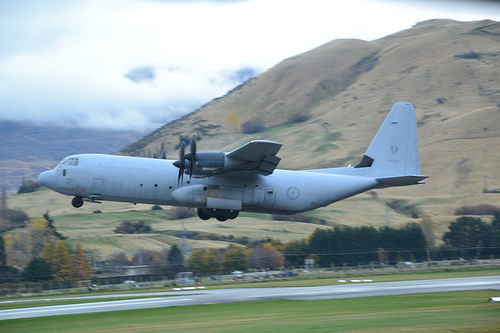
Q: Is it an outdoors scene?
A: Yes, it is outdoors.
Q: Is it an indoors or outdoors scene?
A: It is outdoors.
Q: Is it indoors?
A: No, it is outdoors.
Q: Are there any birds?
A: No, there are no birds.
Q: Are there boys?
A: No, there are no boys.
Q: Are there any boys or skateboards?
A: No, there are no boys or skateboards.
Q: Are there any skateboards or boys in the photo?
A: No, there are no boys or skateboards.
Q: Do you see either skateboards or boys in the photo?
A: No, there are no boys or skateboards.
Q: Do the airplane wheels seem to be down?
A: Yes, the wheels are down.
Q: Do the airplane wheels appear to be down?
A: Yes, the wheels are down.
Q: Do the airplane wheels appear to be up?
A: No, the wheels are down.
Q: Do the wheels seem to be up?
A: No, the wheels are down.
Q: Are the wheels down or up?
A: The wheels are down.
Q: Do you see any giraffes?
A: No, there are no giraffes.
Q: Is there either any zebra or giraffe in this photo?
A: No, there are no giraffes or zebras.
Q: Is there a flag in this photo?
A: No, there are no flags.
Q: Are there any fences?
A: Yes, there is a fence.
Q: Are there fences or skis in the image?
A: Yes, there is a fence.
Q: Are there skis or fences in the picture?
A: Yes, there is a fence.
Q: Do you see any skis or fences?
A: Yes, there is a fence.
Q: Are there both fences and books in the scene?
A: No, there is a fence but no books.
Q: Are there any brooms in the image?
A: No, there are no brooms.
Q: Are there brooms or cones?
A: No, there are no brooms or cones.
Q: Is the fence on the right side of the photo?
A: Yes, the fence is on the right of the image.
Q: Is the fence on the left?
A: No, the fence is on the right of the image.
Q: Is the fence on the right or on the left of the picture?
A: The fence is on the right of the image.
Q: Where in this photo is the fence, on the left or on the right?
A: The fence is on the right of the image.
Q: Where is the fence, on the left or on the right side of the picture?
A: The fence is on the right of the image.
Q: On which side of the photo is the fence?
A: The fence is on the right of the image.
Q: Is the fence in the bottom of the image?
A: Yes, the fence is in the bottom of the image.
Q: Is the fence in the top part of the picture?
A: No, the fence is in the bottom of the image.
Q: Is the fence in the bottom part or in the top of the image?
A: The fence is in the bottom of the image.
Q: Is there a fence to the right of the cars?
A: Yes, there is a fence to the right of the cars.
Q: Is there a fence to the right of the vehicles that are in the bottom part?
A: Yes, there is a fence to the right of the cars.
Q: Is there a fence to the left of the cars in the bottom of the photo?
A: No, the fence is to the right of the cars.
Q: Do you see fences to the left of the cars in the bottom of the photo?
A: No, the fence is to the right of the cars.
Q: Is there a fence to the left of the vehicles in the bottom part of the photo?
A: No, the fence is to the right of the cars.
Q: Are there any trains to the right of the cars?
A: No, there is a fence to the right of the cars.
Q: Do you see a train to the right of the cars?
A: No, there is a fence to the right of the cars.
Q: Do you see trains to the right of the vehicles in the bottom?
A: No, there is a fence to the right of the cars.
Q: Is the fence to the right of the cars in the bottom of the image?
A: Yes, the fence is to the right of the cars.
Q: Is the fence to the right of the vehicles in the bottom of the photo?
A: Yes, the fence is to the right of the cars.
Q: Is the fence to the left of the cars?
A: No, the fence is to the right of the cars.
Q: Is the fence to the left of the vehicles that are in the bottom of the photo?
A: No, the fence is to the right of the cars.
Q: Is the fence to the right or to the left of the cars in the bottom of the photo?
A: The fence is to the right of the cars.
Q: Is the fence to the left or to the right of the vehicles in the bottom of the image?
A: The fence is to the right of the cars.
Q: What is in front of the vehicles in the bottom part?
A: The fence is in front of the cars.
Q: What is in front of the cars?
A: The fence is in front of the cars.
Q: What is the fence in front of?
A: The fence is in front of the cars.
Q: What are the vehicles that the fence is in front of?
A: The vehicles are cars.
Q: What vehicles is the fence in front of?
A: The fence is in front of the cars.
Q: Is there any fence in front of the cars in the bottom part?
A: Yes, there is a fence in front of the cars.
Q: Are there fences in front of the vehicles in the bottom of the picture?
A: Yes, there is a fence in front of the cars.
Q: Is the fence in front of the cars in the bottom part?
A: Yes, the fence is in front of the cars.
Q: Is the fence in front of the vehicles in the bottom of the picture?
A: Yes, the fence is in front of the cars.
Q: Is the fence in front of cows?
A: No, the fence is in front of the cars.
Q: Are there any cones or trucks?
A: No, there are no trucks or cones.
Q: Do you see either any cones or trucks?
A: No, there are no trucks or cones.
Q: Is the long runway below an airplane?
A: Yes, the runway is below an airplane.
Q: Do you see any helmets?
A: No, there are no helmets.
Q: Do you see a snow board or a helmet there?
A: No, there are no helmets or snowboards.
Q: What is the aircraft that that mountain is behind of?
A: The aircraft is an airplane.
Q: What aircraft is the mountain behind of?
A: The mountain is behind the plane.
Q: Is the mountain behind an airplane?
A: Yes, the mountain is behind an airplane.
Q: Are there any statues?
A: No, there are no statues.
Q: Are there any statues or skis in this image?
A: No, there are no statues or skis.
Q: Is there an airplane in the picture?
A: Yes, there is an airplane.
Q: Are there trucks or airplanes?
A: Yes, there is an airplane.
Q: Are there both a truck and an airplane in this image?
A: No, there is an airplane but no trucks.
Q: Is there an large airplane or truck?
A: Yes, there is a large airplane.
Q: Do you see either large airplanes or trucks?
A: Yes, there is a large airplane.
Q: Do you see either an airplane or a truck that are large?
A: Yes, the airplane is large.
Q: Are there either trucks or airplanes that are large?
A: Yes, the airplane is large.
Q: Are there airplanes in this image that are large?
A: Yes, there is a large airplane.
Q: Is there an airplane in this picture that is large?
A: Yes, there is an airplane that is large.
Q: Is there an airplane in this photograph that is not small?
A: Yes, there is a large airplane.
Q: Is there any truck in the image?
A: No, there are no trucks.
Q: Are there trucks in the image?
A: No, there are no trucks.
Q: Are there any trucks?
A: No, there are no trucks.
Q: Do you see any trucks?
A: No, there are no trucks.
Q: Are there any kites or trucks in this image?
A: No, there are no trucks or kites.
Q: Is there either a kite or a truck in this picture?
A: No, there are no trucks or kites.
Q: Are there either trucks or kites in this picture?
A: No, there are no trucks or kites.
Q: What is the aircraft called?
A: The aircraft is an airplane.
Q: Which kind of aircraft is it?
A: The aircraft is an airplane.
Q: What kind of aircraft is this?
A: That is an airplane.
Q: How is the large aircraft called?
A: The aircraft is an airplane.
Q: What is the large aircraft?
A: The aircraft is an airplane.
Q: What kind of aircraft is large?
A: The aircraft is an airplane.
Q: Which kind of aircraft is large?
A: The aircraft is an airplane.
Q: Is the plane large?
A: Yes, the plane is large.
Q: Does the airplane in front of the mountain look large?
A: Yes, the airplane is large.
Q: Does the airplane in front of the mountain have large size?
A: Yes, the airplane is large.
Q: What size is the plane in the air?
A: The airplane is large.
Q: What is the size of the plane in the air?
A: The airplane is large.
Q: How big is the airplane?
A: The airplane is large.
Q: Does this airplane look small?
A: No, the airplane is large.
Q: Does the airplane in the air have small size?
A: No, the airplane is large.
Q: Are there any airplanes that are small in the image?
A: No, there is an airplane but it is large.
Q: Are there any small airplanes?
A: No, there is an airplane but it is large.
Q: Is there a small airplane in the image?
A: No, there is an airplane but it is large.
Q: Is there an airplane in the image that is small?
A: No, there is an airplane but it is large.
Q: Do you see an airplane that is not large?
A: No, there is an airplane but it is large.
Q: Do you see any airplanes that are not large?
A: No, there is an airplane but it is large.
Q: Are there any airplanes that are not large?
A: No, there is an airplane but it is large.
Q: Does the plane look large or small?
A: The plane is large.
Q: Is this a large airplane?
A: Yes, this is a large airplane.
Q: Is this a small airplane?
A: No, this is a large airplane.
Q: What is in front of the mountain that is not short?
A: The plane is in front of the mountain.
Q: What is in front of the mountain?
A: The plane is in front of the mountain.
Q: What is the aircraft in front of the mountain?
A: The aircraft is an airplane.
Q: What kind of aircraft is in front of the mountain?
A: The aircraft is an airplane.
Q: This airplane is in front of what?
A: The airplane is in front of the mountain.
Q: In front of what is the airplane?
A: The airplane is in front of the mountain.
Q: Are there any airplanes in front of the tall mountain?
A: Yes, there is an airplane in front of the mountain.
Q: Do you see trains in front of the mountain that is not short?
A: No, there is an airplane in front of the mountain.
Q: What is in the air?
A: The airplane is in the air.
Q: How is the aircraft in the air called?
A: The aircraft is an airplane.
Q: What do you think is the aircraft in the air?
A: The aircraft is an airplane.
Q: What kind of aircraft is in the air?
A: The aircraft is an airplane.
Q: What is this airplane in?
A: The airplane is in the air.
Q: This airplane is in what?
A: The airplane is in the air.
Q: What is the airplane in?
A: The airplane is in the air.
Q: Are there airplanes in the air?
A: Yes, there is an airplane in the air.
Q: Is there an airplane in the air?
A: Yes, there is an airplane in the air.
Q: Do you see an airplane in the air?
A: Yes, there is an airplane in the air.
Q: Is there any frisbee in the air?
A: No, there is an airplane in the air.